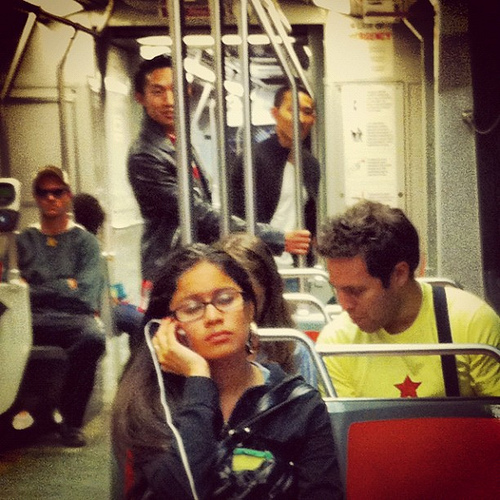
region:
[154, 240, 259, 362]
the head of a woman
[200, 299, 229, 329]
the nose of a woman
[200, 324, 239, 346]
the mouth of a woman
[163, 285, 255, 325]
a pair of sunglasses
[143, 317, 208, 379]
the hand of the woman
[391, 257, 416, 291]
the ear of the man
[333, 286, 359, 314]
the nose of the man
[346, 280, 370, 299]
the eye of the man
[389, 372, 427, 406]
a red star on the shirt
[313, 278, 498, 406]
a yellow shirt on the man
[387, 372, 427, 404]
A RED STAR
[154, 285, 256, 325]
A PAIR OF GLASSES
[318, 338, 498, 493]
AN EMPTY SEAT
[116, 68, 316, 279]
A MAN HOLDING ON TO A POLE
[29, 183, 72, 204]
A PAIR OF SUNGLASSES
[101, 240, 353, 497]
A GIRL WITH HER EYES CLOSED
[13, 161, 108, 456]
A MAN WITH HIS ARMS CROSSED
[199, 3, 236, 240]
A METAL BUS POLE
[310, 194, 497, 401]
A MAN WITH A YELLOW SHIRT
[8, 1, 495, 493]
A PICTURE OF PEOPLE ON THE BUS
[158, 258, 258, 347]
Young woman is wearing eyeglasses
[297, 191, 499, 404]
Man is wearing a yellow shirt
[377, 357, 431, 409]
Man has a red star on his chest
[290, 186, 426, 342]
Man's hair is short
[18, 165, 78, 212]
Man is wearing sunglasses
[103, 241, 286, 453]
Woman has long dark hair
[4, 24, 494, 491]
People are inside a subway train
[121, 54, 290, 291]
Man is wearing a leather jacket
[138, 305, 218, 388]
Woman is holding a electronic device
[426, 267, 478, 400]
Man has a black strap around his shoulder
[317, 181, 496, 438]
man in a yellow shirt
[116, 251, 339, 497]
woman on a cell phone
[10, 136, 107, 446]
man in a hat and sunglasses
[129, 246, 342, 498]
woman wearing glasses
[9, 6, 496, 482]
people riding on public transportation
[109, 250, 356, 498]
woman in a black jacket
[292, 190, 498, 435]
man with short brown hair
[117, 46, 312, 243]
twom men standing on a rail car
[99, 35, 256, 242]
man wearing a black jacket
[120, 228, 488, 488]
three people sitting down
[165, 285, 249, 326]
eye glasses on woman's face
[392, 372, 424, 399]
small, red star on man's shirt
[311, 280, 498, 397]
a light yellow tee shirt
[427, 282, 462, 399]
a black strap on man's shoulder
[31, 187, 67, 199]
dark sun glasses on man's face.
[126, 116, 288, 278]
a black, leather jacket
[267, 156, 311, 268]
a white tee shirt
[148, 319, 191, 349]
a phone next to the woman's ear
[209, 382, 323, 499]
a black, leather purse.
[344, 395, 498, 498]
a red seat next to the woman